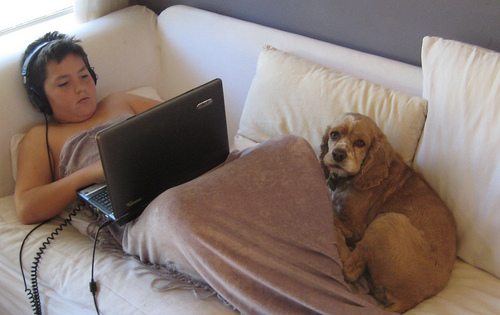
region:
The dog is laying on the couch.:
[327, 133, 449, 295]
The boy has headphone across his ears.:
[17, 46, 106, 121]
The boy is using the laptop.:
[53, 63, 268, 190]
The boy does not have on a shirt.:
[41, 75, 229, 225]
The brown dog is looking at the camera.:
[314, 97, 443, 282]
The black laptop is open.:
[35, 116, 283, 219]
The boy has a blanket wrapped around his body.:
[64, 114, 364, 286]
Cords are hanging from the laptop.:
[25, 207, 97, 314]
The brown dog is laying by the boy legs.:
[210, 126, 497, 296]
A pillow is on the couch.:
[238, 47, 425, 188]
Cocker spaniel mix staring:
[312, 103, 445, 313]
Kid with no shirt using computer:
[13, 30, 244, 232]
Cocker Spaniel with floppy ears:
[317, 111, 409, 191]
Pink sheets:
[125, 126, 414, 313]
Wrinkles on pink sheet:
[172, 190, 413, 312]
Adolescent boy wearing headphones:
[9, 19, 115, 122]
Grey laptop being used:
[78, 76, 232, 225]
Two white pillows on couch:
[231, 33, 498, 277]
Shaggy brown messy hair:
[7, 21, 105, 121]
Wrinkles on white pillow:
[292, 58, 424, 139]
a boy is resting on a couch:
[12, 31, 392, 312]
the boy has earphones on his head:
[20, 30, 96, 118]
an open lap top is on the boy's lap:
[71, 75, 231, 235]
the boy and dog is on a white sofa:
[5, 5, 496, 310]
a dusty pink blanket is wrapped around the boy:
[75, 110, 386, 311]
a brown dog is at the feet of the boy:
[282, 106, 464, 311]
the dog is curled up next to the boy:
[317, 112, 458, 302]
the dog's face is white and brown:
[318, 110, 378, 180]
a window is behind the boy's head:
[0, 3, 180, 104]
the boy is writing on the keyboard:
[38, 49, 228, 226]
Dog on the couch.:
[313, 104, 465, 311]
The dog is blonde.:
[315, 95, 460, 312]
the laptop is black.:
[74, 70, 229, 227]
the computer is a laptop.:
[72, 72, 236, 225]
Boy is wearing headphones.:
[18, 30, 105, 113]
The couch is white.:
[3, 6, 498, 310]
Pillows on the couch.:
[227, 26, 499, 276]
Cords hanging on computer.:
[10, 192, 116, 313]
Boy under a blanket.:
[52, 103, 392, 313]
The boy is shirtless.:
[5, 75, 173, 222]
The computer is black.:
[67, 70, 234, 230]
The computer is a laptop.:
[76, 66, 228, 234]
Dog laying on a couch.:
[307, 100, 467, 311]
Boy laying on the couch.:
[16, 27, 390, 308]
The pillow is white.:
[228, 25, 498, 273]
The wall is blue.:
[127, 0, 498, 72]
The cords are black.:
[15, 197, 120, 312]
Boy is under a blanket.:
[52, 102, 400, 313]